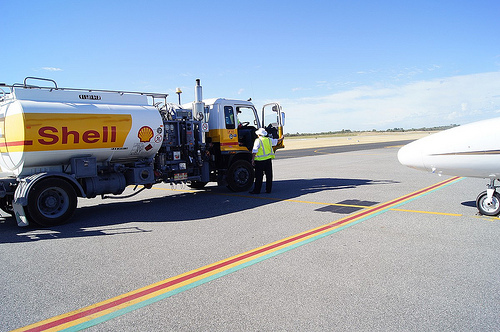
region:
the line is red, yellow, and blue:
[123, 236, 240, 296]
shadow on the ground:
[80, 173, 394, 233]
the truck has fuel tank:
[4, 62, 330, 235]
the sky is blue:
[75, 9, 316, 81]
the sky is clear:
[62, 7, 256, 57]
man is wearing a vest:
[243, 135, 294, 165]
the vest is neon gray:
[243, 135, 295, 171]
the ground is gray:
[141, 206, 211, 271]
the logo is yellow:
[130, 114, 188, 175]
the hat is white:
[246, 125, 280, 139]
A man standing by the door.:
[235, 126, 287, 188]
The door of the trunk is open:
[253, 107, 298, 152]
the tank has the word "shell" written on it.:
[33, 107, 128, 147]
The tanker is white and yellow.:
[16, 88, 156, 165]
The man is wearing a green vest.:
[248, 140, 283, 162]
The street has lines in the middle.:
[166, 206, 395, 269]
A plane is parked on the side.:
[400, 94, 499, 193]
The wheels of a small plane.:
[462, 184, 498, 215]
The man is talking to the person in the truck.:
[231, 108, 288, 180]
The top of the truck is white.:
[218, 96, 273, 125]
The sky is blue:
[257, 11, 492, 167]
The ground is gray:
[162, 242, 362, 318]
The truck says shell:
[28, 101, 158, 179]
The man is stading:
[231, 116, 329, 248]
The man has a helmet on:
[250, 121, 279, 145]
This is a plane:
[374, 103, 498, 214]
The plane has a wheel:
[466, 168, 497, 226]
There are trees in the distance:
[304, 65, 387, 243]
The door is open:
[230, 83, 345, 230]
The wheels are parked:
[11, 171, 146, 260]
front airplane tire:
[468, 184, 498, 213]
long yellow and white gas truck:
[0, 73, 287, 227]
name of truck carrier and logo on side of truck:
[27, 118, 157, 146]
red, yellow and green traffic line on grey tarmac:
[7, 173, 497, 329]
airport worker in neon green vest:
[245, 126, 282, 195]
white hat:
[253, 126, 268, 136]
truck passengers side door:
[257, 103, 287, 150]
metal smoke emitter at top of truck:
[189, 76, 206, 111]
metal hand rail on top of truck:
[14, 75, 61, 87]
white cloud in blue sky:
[361, 74, 443, 112]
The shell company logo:
[36, 122, 121, 152]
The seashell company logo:
[132, 114, 165, 151]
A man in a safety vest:
[241, 122, 287, 186]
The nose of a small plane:
[372, 106, 484, 211]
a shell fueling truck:
[10, 56, 347, 235]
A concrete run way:
[213, 208, 436, 320]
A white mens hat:
[249, 118, 271, 139]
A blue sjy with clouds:
[318, 44, 418, 147]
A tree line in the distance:
[292, 117, 414, 139]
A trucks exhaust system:
[183, 68, 215, 141]